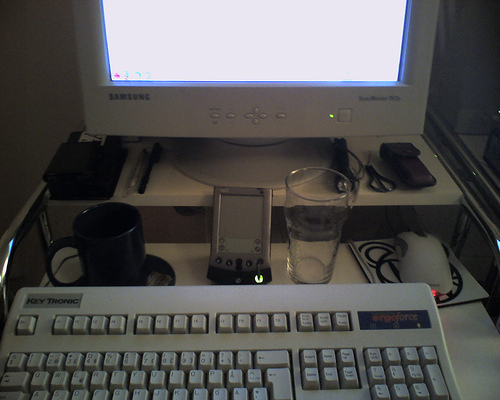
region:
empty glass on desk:
[280, 160, 342, 280]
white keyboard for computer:
[4, 316, 441, 396]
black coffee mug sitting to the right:
[46, 199, 173, 282]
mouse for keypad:
[374, 210, 464, 298]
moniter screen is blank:
[119, 0, 406, 87]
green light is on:
[313, 96, 354, 138]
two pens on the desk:
[132, 142, 157, 197]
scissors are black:
[350, 147, 403, 199]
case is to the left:
[381, 137, 446, 194]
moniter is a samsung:
[78, 0, 423, 136]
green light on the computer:
[310, 98, 357, 131]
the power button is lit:
[310, 101, 345, 132]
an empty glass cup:
[258, 150, 353, 270]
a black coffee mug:
[22, 188, 170, 280]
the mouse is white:
[377, 217, 459, 309]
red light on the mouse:
[407, 265, 457, 310]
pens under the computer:
[121, 137, 170, 193]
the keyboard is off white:
[1, 267, 462, 394]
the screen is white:
[82, 0, 412, 91]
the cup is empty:
[20, 196, 164, 273]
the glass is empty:
[281, 166, 333, 285]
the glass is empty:
[280, 152, 360, 294]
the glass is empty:
[281, 150, 367, 333]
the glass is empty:
[291, 158, 361, 286]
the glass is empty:
[276, 158, 361, 308]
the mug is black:
[51, 198, 166, 285]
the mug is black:
[31, 195, 201, 320]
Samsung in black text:
[106, 91, 151, 102]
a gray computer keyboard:
[1, 285, 463, 398]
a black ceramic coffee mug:
[41, 202, 146, 284]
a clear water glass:
[287, 167, 349, 284]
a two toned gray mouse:
[396, 231, 453, 293]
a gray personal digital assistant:
[212, 184, 272, 271]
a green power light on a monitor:
[327, 111, 333, 116]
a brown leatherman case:
[380, 141, 438, 189]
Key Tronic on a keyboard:
[23, 293, 79, 306]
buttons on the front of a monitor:
[211, 106, 288, 127]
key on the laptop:
[271, 311, 291, 332]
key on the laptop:
[298, 310, 312, 331]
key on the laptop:
[318, 310, 327, 331]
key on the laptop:
[331, 310, 352, 329]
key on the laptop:
[216, 312, 235, 334]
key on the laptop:
[191, 313, 213, 334]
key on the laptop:
[170, 313, 185, 331]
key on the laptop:
[132, 311, 156, 336]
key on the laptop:
[108, 313, 127, 335]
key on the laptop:
[52, 312, 74, 335]